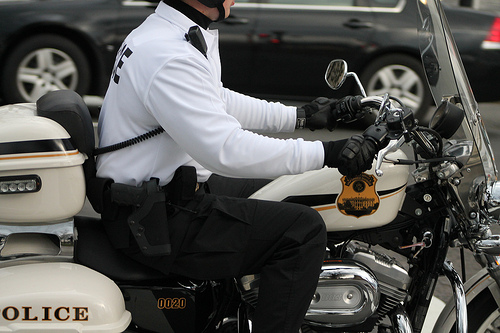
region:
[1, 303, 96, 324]
part of the word "POLICE"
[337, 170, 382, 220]
police shield emblem on a bike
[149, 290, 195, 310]
number on a bike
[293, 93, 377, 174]
black biking gloves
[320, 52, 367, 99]
rear view mirror on a bike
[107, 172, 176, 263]
gun in a side holster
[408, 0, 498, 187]
windshield on a bike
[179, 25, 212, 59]
radio on an officer's shoulder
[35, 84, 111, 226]
back part of a bike's seat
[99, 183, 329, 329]
black colored pants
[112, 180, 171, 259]
Police gun in holster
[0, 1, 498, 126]
Black car in the background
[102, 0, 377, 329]
Police officer on a bike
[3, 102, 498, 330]
White police motorcycle with black and yellow stripes.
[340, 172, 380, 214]
Yellow White House police emblem.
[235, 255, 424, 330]
Shiny silver motorcycle motor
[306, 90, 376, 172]
Black riding gloves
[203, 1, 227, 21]
Motorcycle helmet neck strap.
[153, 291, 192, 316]
Motorcycle officer identification number 20.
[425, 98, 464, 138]
Motorcycle speedometer.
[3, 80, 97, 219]
back storage for motorcycle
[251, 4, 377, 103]
black car driving by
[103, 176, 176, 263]
police issued gun for protection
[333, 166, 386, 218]
police badge on bike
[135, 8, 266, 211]
police officer riding bike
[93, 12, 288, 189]
white shirt for uniform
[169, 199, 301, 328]
black pants for uniform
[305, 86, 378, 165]
black motorcycle gloves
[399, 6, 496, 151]
bullet proof protection shield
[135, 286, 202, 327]
bike issued number for bike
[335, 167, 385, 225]
yellow and black police badge emblem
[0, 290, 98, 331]
black and yellow police word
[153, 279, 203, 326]
black and yellow 0020 emblem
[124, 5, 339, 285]
police officer in black and white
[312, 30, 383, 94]
mirror of motorcycle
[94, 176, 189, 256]
gun on man's belt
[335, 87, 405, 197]
motorcycles handlebars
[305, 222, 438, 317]
silver engine of motorcycle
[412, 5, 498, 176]
front windshield of motorcycle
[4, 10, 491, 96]
black car in background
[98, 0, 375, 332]
a police officer on a motorcycle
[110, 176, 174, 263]
a black gun holster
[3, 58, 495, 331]
a police motorcycle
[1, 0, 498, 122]
a black car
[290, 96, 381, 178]
hands wearing motorcycle gloves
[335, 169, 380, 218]
a police logo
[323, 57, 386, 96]
a motorcycle's rearview mirror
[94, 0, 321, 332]
a police officer wearing a black and white uniform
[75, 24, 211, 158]
a handheld radio transmitter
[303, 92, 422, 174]
a motorcycle's handlebars being used